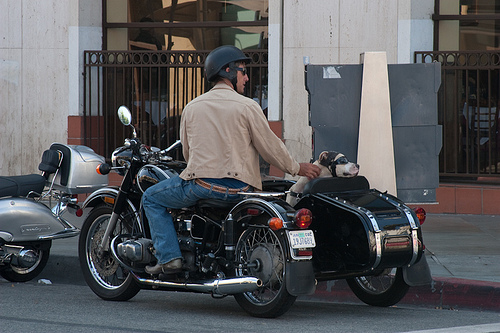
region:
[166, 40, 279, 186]
this is a man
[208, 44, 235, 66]
this is a helmet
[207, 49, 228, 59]
the helmet is black in color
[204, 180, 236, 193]
this is the belt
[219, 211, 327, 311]
this is a motorbike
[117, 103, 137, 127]
this is a mirror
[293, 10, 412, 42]
this is a wall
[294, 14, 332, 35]
the wall is white in color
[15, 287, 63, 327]
this is the road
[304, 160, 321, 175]
the man is light skinned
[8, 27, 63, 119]
this is a wall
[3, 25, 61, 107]
the wall is white in color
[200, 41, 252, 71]
this is a helmet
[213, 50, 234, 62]
the helmet is black in color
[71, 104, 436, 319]
this is a tricycle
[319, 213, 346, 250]
the tricycle is black in color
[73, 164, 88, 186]
the motorcycle is grey in color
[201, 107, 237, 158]
the jacket is brown in color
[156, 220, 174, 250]
the trouser is blue in color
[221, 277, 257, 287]
the exhaust pipe is metallic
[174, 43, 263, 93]
A BLACK SAFETY HELMET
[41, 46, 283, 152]
A METAL GATE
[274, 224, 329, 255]
A MOTORCYCLE LICENSE PLATE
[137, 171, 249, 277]
A PAIR OF BLUE JEANS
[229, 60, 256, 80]
A PAIR OF SUNGLASSES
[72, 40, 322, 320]
A PICTURE OF A MAN SITTING ON A MOTORCYCLE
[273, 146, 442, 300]
A DOG SITTING IN A SIDECAR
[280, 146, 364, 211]
A DOG WEARING GOGGLES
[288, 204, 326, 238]
A MOTORCYCLE BRAKE LIGHT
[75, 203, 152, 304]
FRONT MOTORCYCLE TIRE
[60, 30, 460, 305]
man on motorcycle and dog in sidecar by curb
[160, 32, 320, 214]
biker in black helmet turning around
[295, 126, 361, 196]
dog in strap and goggles looking back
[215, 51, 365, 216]
rider's arm on dog's shoulder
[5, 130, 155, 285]
silver motorbike in front of motorcycle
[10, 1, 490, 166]
black railing between thick stone pillars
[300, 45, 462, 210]
slabs of dark gray stone in tan holder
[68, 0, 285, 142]
large reflective window behind railing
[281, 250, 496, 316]
dark red stripe along curb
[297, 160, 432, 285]
black sidecar with silver straps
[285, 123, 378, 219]
dog in the motorcycle side car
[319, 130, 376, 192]
dog is wearing goggles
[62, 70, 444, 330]
motorcycle is parked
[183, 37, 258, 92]
man's helmet is black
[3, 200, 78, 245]
motorcycle is silver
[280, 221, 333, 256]
license plat of the motorcycle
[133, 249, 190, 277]
man is wearing boots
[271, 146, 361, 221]
man has his hand on the dog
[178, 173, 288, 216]
man is wearing a brown belt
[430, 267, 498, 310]
the curb is painted red